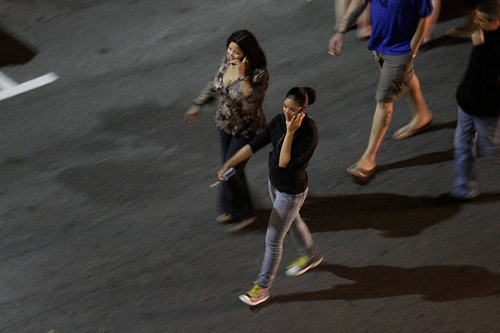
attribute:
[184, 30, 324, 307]
women — walking, talking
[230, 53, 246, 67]
phone — black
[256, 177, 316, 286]
jeans — grey, light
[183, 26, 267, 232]
woman — light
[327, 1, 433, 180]
man — walking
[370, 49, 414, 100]
shorts — brown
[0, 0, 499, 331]
road — tarmacked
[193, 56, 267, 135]
blouse — flowered, long-sleeved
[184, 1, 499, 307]
people — walking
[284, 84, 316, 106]
hair — dark, up, black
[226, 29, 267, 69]
hair — dark, long, black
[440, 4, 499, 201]
man — walking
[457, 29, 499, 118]
shirt — black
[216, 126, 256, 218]
pants — black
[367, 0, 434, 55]
shirt — blue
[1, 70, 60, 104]
line — white, painted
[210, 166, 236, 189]
purse — small